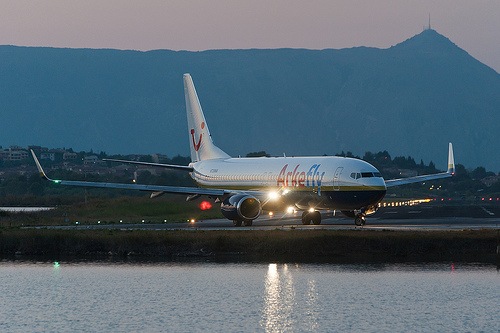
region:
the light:
[261, 175, 316, 256]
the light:
[220, 170, 354, 260]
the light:
[226, 172, 331, 324]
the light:
[249, 182, 300, 237]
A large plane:
[23, 51, 480, 241]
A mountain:
[28, 23, 499, 162]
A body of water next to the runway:
[19, 258, 499, 325]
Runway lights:
[381, 190, 446, 215]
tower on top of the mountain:
[405, 8, 460, 34]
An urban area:
[0, 142, 127, 178]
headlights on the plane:
[249, 182, 316, 229]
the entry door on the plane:
[329, 160, 352, 198]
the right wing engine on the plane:
[202, 183, 317, 224]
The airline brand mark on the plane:
[259, 155, 336, 194]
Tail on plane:
[165, 65, 226, 157]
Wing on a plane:
[389, 137, 463, 189]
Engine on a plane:
[220, 188, 272, 224]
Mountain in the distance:
[6, 26, 385, 73]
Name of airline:
[270, 162, 330, 190]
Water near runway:
[69, 267, 179, 312]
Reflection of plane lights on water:
[252, 259, 323, 326]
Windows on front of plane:
[346, 168, 389, 183]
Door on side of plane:
[327, 162, 354, 193]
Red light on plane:
[190, 190, 218, 212]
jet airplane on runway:
[179, 68, 458, 237]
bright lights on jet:
[257, 182, 321, 225]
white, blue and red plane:
[192, 113, 352, 207]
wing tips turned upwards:
[18, 135, 128, 213]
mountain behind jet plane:
[303, 20, 498, 183]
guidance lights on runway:
[380, 190, 497, 222]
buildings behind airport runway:
[5, 116, 181, 221]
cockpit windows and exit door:
[331, 161, 389, 208]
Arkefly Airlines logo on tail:
[178, 91, 238, 181]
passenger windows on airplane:
[200, 163, 312, 185]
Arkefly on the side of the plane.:
[264, 160, 338, 195]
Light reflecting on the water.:
[255, 258, 328, 330]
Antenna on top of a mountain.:
[416, 0, 443, 37]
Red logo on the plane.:
[178, 114, 213, 159]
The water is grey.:
[89, 280, 209, 322]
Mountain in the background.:
[6, 26, 498, 185]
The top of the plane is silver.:
[196, 157, 385, 184]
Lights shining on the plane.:
[261, 187, 323, 222]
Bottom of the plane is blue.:
[223, 190, 384, 215]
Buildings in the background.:
[2, 140, 183, 179]